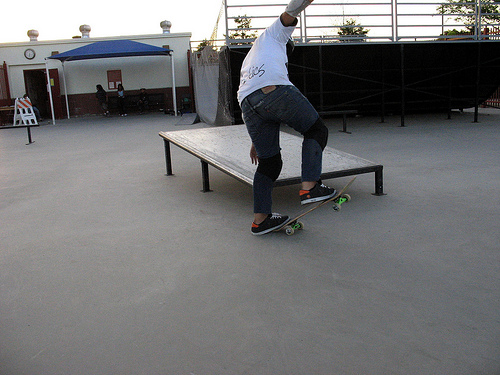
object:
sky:
[1, 2, 469, 38]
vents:
[70, 35, 85, 41]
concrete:
[1, 33, 191, 114]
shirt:
[236, 15, 299, 104]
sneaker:
[296, 180, 338, 205]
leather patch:
[260, 85, 278, 94]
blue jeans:
[236, 83, 327, 212]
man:
[233, 2, 345, 235]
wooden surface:
[158, 125, 380, 186]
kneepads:
[309, 120, 331, 151]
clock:
[22, 47, 37, 62]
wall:
[224, 46, 500, 113]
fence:
[223, 0, 499, 46]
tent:
[49, 23, 158, 98]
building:
[0, 19, 195, 127]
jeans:
[240, 85, 327, 213]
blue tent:
[43, 37, 175, 127]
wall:
[0, 32, 196, 99]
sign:
[12, 96, 39, 126]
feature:
[159, 125, 382, 198]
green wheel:
[333, 202, 341, 212]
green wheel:
[343, 194, 351, 203]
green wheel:
[285, 226, 293, 235]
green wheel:
[295, 222, 303, 231]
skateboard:
[270, 176, 355, 234]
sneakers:
[253, 208, 290, 237]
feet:
[245, 181, 335, 238]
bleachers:
[190, 0, 483, 125]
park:
[0, 0, 499, 375]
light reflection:
[157, 126, 222, 158]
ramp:
[157, 124, 385, 206]